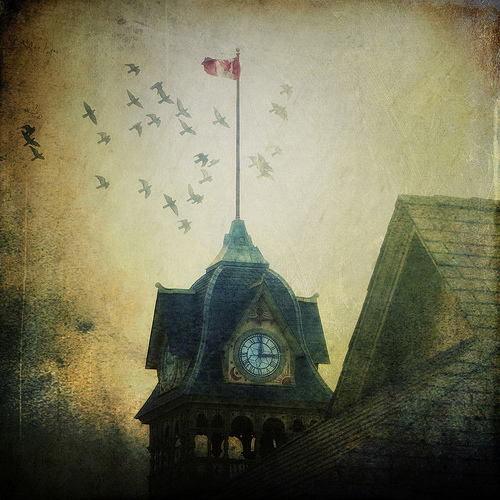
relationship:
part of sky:
[3, 2, 500, 406] [2, 1, 499, 450]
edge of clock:
[242, 328, 284, 379] [233, 326, 284, 379]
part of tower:
[137, 218, 313, 441] [148, 34, 331, 465]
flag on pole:
[204, 56, 240, 82] [228, 48, 244, 225]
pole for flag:
[228, 48, 244, 225] [204, 56, 240, 82]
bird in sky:
[165, 194, 179, 215] [2, 1, 499, 450]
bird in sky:
[93, 178, 111, 191] [2, 1, 499, 450]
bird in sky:
[28, 146, 44, 163] [2, 1, 499, 450]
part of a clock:
[233, 326, 284, 379] [233, 326, 287, 383]